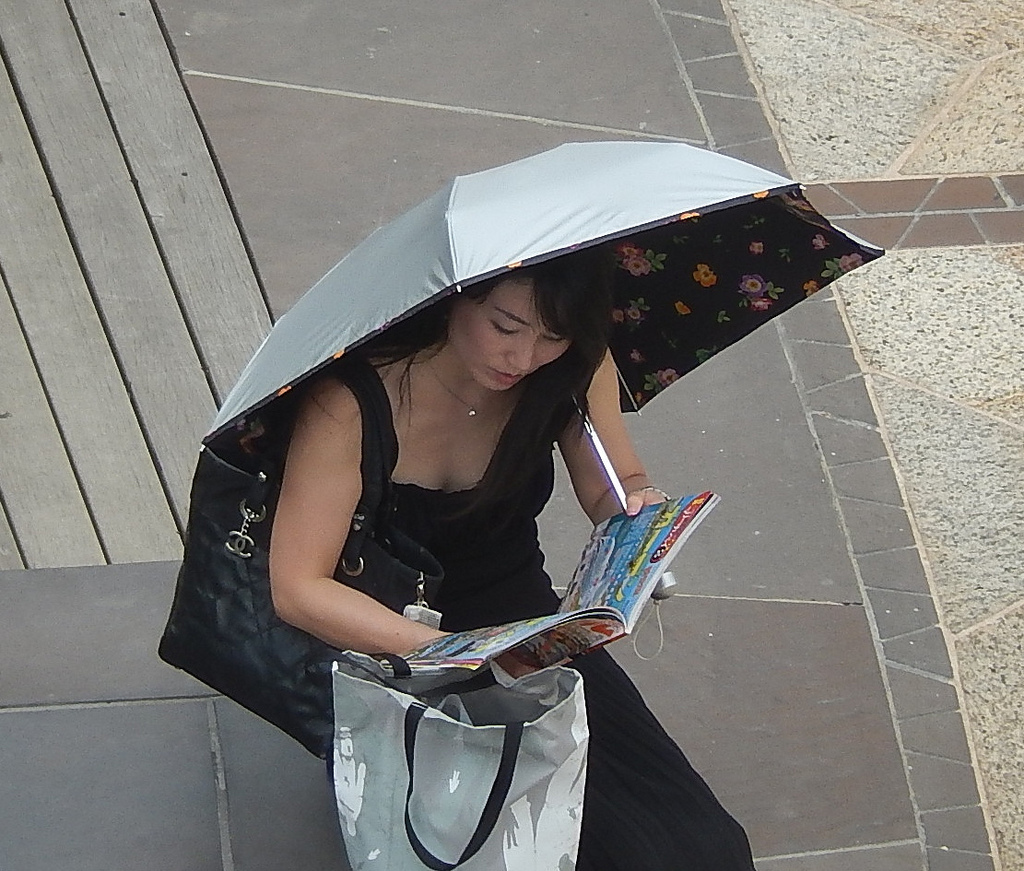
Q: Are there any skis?
A: No, there are no skis.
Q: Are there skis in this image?
A: No, there are no skis.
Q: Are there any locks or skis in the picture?
A: No, there are no skis or locks.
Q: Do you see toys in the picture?
A: No, there are no toys.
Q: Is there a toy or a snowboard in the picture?
A: No, there are no toys or snowboards.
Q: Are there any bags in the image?
A: Yes, there is a bag.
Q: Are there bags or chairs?
A: Yes, there is a bag.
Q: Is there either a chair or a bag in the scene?
A: Yes, there is a bag.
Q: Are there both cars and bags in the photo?
A: No, there is a bag but no cars.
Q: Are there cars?
A: No, there are no cars.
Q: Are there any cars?
A: No, there are no cars.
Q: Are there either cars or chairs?
A: No, there are no cars or chairs.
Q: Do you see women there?
A: Yes, there is a woman.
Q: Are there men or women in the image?
A: Yes, there is a woman.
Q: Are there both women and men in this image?
A: No, there is a woman but no men.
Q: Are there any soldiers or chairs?
A: No, there are no chairs or soldiers.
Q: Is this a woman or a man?
A: This is a woman.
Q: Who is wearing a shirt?
A: The woman is wearing a shirt.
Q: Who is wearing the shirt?
A: The woman is wearing a shirt.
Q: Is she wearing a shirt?
A: Yes, the woman is wearing a shirt.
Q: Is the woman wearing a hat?
A: No, the woman is wearing a shirt.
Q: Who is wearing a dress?
A: The woman is wearing a dress.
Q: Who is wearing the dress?
A: The woman is wearing a dress.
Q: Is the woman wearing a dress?
A: Yes, the woman is wearing a dress.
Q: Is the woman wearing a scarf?
A: No, the woman is wearing a dress.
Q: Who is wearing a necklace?
A: The woman is wearing a necklace.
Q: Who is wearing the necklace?
A: The woman is wearing a necklace.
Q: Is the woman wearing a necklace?
A: Yes, the woman is wearing a necklace.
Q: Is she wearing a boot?
A: No, the woman is wearing a necklace.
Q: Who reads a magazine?
A: The woman reads a magazine.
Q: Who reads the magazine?
A: The woman reads a magazine.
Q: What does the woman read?
A: The woman reads a magazine.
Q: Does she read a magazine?
A: Yes, the woman reads a magazine.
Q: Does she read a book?
A: No, the woman reads a magazine.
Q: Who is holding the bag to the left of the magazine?
A: The woman is holding the bag.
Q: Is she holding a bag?
A: Yes, the woman is holding a bag.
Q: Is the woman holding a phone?
A: No, the woman is holding a bag.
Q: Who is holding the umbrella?
A: The woman is holding the umbrella.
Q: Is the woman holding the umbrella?
A: Yes, the woman is holding the umbrella.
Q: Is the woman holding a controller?
A: No, the woman is holding the umbrella.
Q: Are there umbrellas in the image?
A: Yes, there is an umbrella.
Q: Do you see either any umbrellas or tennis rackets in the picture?
A: Yes, there is an umbrella.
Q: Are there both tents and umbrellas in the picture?
A: No, there is an umbrella but no tents.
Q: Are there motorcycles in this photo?
A: No, there are no motorcycles.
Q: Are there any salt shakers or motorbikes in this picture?
A: No, there are no motorbikes or salt shakers.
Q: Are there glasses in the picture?
A: No, there are no glasses.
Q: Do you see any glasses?
A: No, there are no glasses.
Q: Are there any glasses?
A: No, there are no glasses.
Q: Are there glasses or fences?
A: No, there are no glasses or fences.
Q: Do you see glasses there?
A: No, there are no glasses.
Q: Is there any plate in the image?
A: No, there are no plates.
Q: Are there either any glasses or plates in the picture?
A: No, there are no plates or glasses.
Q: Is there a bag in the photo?
A: Yes, there is a bag.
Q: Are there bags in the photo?
A: Yes, there is a bag.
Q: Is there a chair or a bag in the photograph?
A: Yes, there is a bag.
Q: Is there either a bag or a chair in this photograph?
A: Yes, there is a bag.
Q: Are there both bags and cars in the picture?
A: No, there is a bag but no cars.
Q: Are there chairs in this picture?
A: No, there are no chairs.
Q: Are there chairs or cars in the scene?
A: No, there are no chairs or cars.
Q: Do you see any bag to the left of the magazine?
A: Yes, there is a bag to the left of the magazine.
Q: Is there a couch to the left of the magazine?
A: No, there is a bag to the left of the magazine.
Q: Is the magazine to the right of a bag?
A: Yes, the magazine is to the right of a bag.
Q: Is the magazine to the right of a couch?
A: No, the magazine is to the right of a bag.